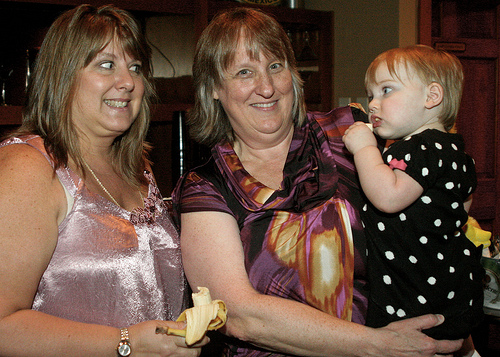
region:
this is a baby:
[353, 43, 478, 342]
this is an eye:
[88, 52, 125, 82]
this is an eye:
[123, 56, 145, 81]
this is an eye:
[265, 51, 288, 77]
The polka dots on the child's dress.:
[360, 130, 482, 338]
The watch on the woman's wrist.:
[119, 327, 130, 355]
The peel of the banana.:
[173, 304, 227, 345]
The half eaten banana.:
[192, 287, 209, 304]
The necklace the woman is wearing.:
[75, 147, 145, 209]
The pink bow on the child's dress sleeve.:
[388, 159, 407, 168]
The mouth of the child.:
[368, 115, 384, 125]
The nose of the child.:
[367, 101, 377, 110]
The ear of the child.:
[425, 80, 443, 107]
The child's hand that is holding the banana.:
[342, 119, 374, 149]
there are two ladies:
[50, 45, 380, 267]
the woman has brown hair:
[24, 25, 308, 179]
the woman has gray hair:
[165, 35, 333, 165]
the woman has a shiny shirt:
[55, 165, 179, 313]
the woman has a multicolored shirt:
[217, 147, 367, 284]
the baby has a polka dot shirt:
[344, 118, 494, 329]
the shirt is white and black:
[370, 187, 462, 295]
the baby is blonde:
[342, 40, 482, 124]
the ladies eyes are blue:
[90, 41, 325, 112]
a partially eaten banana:
[157, 288, 227, 344]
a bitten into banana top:
[190, 287, 207, 297]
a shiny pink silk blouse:
[1, 133, 185, 326]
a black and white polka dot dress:
[363, 132, 483, 339]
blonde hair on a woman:
[192, 8, 307, 143]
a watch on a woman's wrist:
[117, 325, 133, 355]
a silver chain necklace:
[74, 143, 144, 213]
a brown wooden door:
[417, 0, 499, 254]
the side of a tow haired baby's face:
[362, 45, 463, 137]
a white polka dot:
[419, 234, 426, 246]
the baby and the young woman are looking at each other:
[5, 3, 481, 355]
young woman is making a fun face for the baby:
[3, 5, 484, 347]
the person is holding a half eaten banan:
[4, 3, 226, 354]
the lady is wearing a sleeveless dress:
[5, 5, 209, 352]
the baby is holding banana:
[343, 44, 483, 355]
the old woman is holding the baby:
[183, 9, 485, 355]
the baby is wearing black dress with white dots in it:
[342, 43, 486, 355]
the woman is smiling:
[180, 8, 462, 355]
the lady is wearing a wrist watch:
[1, 3, 208, 352]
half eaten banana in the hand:
[2, 283, 227, 355]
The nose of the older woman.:
[255, 77, 273, 100]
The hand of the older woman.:
[378, 313, 460, 355]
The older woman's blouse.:
[182, 104, 376, 354]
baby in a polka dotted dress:
[339, 40, 486, 355]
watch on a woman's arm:
[114, 319, 135, 355]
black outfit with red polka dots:
[358, 125, 491, 337]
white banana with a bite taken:
[165, 283, 229, 346]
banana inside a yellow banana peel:
[168, 283, 228, 347]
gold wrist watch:
[117, 325, 134, 355]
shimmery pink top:
[4, 127, 187, 327]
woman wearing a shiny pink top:
[1, 4, 185, 355]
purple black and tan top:
[171, 100, 371, 355]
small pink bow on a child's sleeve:
[386, 155, 408, 172]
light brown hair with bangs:
[186, 5, 307, 142]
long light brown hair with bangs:
[9, 3, 156, 190]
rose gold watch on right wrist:
[115, 324, 132, 355]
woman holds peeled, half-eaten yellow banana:
[164, 282, 228, 347]